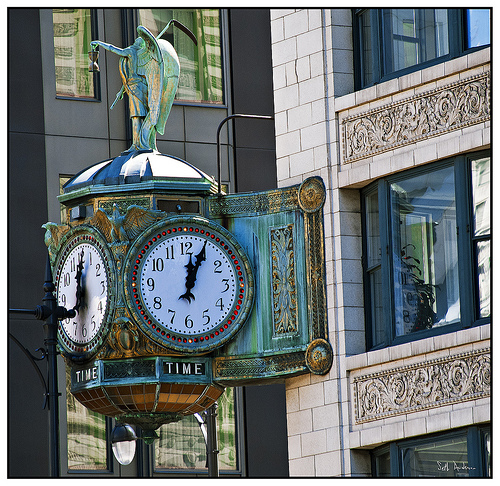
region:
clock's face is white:
[126, 220, 248, 352]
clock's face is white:
[23, 231, 148, 359]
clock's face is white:
[96, 203, 276, 397]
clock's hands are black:
[156, 235, 216, 314]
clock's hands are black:
[166, 235, 236, 337]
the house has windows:
[283, 37, 498, 484]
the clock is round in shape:
[133, 203, 252, 347]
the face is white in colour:
[137, 228, 238, 339]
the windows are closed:
[338, 163, 486, 335]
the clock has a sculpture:
[72, 13, 207, 122]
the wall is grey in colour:
[13, 98, 61, 163]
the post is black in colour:
[10, 252, 80, 452]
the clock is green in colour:
[243, 203, 320, 359]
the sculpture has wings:
[59, 11, 181, 143]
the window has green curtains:
[65, 8, 101, 93]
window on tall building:
[55, 8, 104, 101]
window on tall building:
[157, 6, 203, 104]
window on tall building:
[378, 4, 448, 75]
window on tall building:
[470, 7, 490, 48]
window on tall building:
[390, 162, 458, 336]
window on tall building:
[474, 156, 489, 310]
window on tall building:
[66, 372, 108, 470]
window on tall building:
[152, 386, 233, 467]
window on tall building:
[401, 430, 478, 476]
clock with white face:
[135, 237, 254, 337]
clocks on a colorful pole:
[33, 223, 279, 348]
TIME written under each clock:
[66, 352, 223, 396]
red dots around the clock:
[142, 223, 260, 356]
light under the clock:
[88, 415, 163, 474]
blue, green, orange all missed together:
[43, 175, 339, 402]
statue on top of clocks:
[95, 32, 190, 154]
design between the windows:
[326, 68, 499, 178]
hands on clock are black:
[168, 242, 220, 309]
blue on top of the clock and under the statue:
[61, 138, 230, 190]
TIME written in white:
[63, 364, 213, 389]